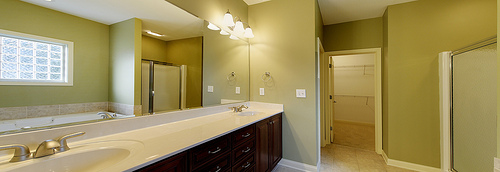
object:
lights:
[205, 11, 255, 42]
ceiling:
[4, 4, 500, 33]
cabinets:
[134, 111, 285, 171]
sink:
[0, 131, 144, 171]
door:
[322, 47, 380, 158]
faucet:
[29, 138, 68, 160]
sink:
[238, 109, 260, 117]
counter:
[1, 108, 280, 171]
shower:
[439, 43, 498, 172]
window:
[0, 32, 80, 84]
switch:
[294, 89, 306, 98]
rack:
[262, 72, 275, 88]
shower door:
[141, 58, 189, 112]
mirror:
[142, 59, 183, 113]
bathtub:
[0, 111, 124, 140]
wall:
[252, 1, 312, 158]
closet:
[331, 49, 376, 152]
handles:
[0, 132, 86, 161]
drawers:
[206, 129, 262, 170]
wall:
[126, 28, 211, 119]